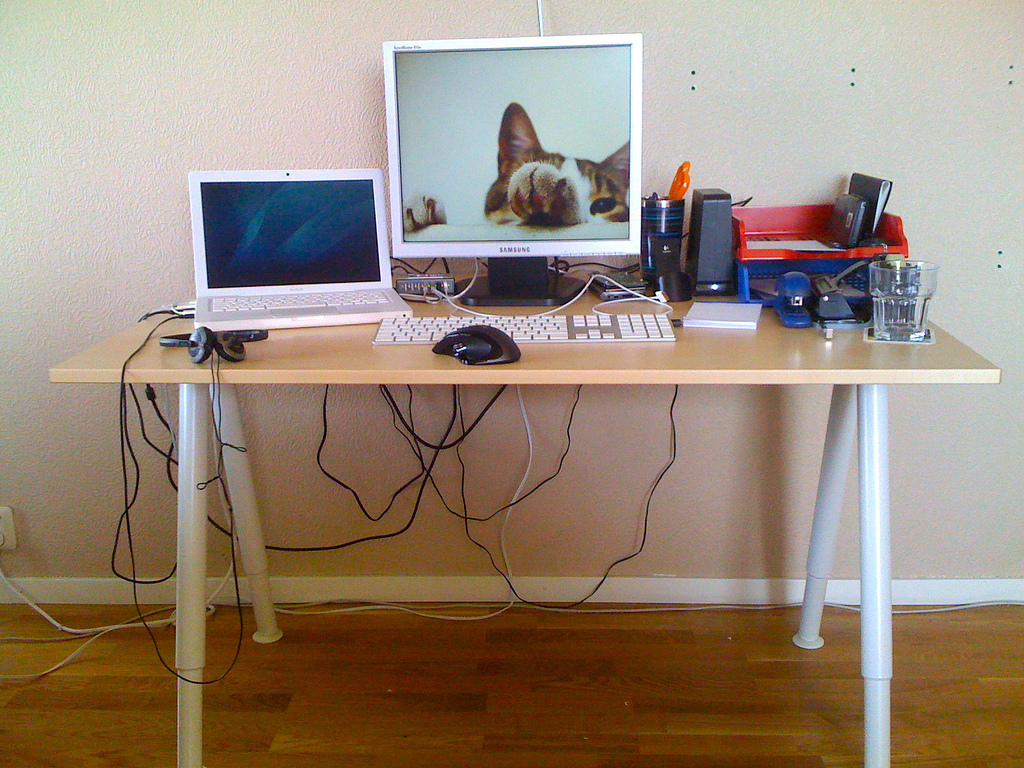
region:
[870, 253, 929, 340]
glass on top of desk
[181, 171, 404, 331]
laptop on top of desk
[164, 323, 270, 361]
headphones on top of desk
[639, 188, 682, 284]
cup on top of desk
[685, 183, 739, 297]
speaker on top of desk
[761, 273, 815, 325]
stapler on top of desk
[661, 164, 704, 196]
orange scissor inside of cup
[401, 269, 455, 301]
modem on top of desk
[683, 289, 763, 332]
paper on top of desk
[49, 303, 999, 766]
a wooden desk with white legs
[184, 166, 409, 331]
a white laptop on a desk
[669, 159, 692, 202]
a pair of orange scissors in a cup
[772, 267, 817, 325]
a blue stapler on a desk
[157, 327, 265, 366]
a pair of black headphones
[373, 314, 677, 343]
a thin white keyboard on a desk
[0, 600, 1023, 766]
a wooden floor underneath a desk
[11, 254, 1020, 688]
a bunch of white and black wires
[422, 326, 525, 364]
black mouse on desk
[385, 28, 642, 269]
monitor on the computer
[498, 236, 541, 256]
logo on the monitor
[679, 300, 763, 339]
white paper note pad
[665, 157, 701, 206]
orange scissors in cup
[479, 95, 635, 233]
cat on the screen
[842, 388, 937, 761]
white leg on the table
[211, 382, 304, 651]
white leg on desk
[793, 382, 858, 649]
white leg on desk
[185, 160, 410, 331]
Open laptop sitting on desk.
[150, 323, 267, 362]
Black headphones laying on top of desk.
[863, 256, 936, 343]
Empty glass sitting on top of desk.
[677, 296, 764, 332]
White pad of paper sitting on top of desk.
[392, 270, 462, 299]
Surge protector laying on top of desk.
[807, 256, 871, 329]
Paper hole punch sitting on top of desk.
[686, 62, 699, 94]
Two holes in the wall.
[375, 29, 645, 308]
Computer monitor sitting on top of desk.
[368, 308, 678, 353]
Computer keyboard sitting on top of desk.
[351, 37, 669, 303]
large monitor on table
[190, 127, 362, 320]
white laptop on table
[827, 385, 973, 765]
table has white legs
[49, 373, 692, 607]
black cords behind table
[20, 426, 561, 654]
white cord on floor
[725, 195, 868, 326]
red and blue inboxes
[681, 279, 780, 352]
white pad of paper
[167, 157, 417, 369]
white laptop with blue screen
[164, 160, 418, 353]
white laptop with blue screen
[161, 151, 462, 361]
white laptop with blue screen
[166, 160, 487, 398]
white laptop with blue screen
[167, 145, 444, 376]
white laptop with blue screen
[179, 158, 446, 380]
white laptop with blue screen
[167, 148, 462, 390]
white laptop with blue screen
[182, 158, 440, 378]
white laptop with blue screen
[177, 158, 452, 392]
white laptop with blue screen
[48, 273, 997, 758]
small table against wall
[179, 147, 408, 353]
small laptop on table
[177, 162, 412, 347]
laptop on table is small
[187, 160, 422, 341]
laptop on table is white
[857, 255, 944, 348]
glass on table is empty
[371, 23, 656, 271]
monitor behind keyboard on table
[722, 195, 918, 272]
red tray stacked on blue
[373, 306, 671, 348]
a keyboard on a desk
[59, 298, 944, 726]
a large wooden desk